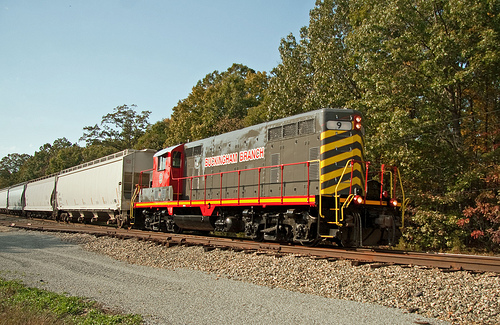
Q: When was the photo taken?
A: Daytime.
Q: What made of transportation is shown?
A: Train.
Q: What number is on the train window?
A: 9.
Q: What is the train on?
A: Track.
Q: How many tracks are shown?
A: One.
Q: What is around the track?
A: Gravel.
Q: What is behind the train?
A: Trees.